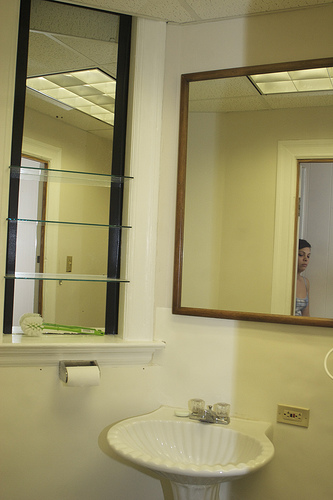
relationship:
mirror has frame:
[168, 54, 328, 339] [173, 58, 331, 328]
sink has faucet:
[105, 403, 275, 499] [186, 404, 229, 425]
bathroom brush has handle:
[22, 314, 106, 338] [45, 325, 108, 338]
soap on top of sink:
[171, 407, 190, 421] [105, 403, 275, 499]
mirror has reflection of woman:
[168, 54, 328, 339] [293, 238, 312, 323]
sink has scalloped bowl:
[105, 403, 275, 499] [120, 419, 267, 473]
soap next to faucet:
[171, 407, 190, 421] [186, 404, 229, 425]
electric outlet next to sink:
[279, 405, 310, 430] [105, 403, 275, 499]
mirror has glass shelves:
[13, 1, 122, 336] [4, 164, 133, 284]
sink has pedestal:
[105, 403, 275, 499] [168, 482, 228, 499]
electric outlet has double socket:
[279, 405, 310, 430] [283, 410, 305, 424]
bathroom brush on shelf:
[22, 314, 106, 338] [6, 313, 126, 344]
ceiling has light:
[27, 3, 120, 151] [27, 70, 116, 124]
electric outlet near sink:
[279, 405, 310, 430] [105, 403, 275, 499]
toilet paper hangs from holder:
[65, 366, 102, 387] [58, 360, 103, 384]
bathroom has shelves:
[4, 1, 333, 498] [4, 164, 133, 284]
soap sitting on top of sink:
[171, 407, 190, 421] [105, 403, 275, 499]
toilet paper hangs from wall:
[65, 366, 102, 387] [4, 1, 333, 498]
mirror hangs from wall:
[168, 54, 328, 339] [4, 1, 333, 498]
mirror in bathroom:
[168, 54, 328, 339] [4, 1, 333, 498]